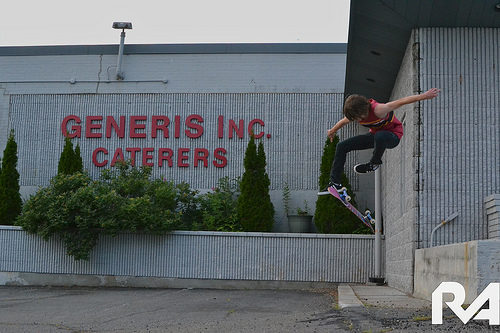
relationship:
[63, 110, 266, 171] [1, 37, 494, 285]
letters on side of building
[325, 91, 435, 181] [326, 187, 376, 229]
guy on top of skateboard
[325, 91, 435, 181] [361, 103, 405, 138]
guy with shirt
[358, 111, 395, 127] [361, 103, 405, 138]
stripes on front of shirt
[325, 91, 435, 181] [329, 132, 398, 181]
guy wearing jeans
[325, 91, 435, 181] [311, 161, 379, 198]
guy wearing shoes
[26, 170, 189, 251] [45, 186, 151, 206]
bushes with flowers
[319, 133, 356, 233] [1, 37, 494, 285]
tree in front of building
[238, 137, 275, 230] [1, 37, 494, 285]
tree in front of building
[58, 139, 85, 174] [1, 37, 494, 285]
tree in front of building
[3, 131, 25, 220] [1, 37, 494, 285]
tree in front of building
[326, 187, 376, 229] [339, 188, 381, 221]
skateboard with wheels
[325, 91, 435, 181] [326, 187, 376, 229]
guy flipping skateboard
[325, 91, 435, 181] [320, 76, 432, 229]
guy doing trick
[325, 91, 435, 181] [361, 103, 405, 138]
guy wearing shirt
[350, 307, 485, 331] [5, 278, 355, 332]
part of pavement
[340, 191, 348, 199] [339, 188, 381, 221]
part of wheels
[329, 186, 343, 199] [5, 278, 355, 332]
part of pavement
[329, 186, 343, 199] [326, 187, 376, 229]
part of skateboard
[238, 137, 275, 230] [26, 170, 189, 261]
tree in bushes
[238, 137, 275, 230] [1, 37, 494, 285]
tree against building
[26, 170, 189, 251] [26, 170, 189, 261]
bushes over bushes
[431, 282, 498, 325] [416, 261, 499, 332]
ra in corner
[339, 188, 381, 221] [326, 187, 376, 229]
wheels on bottom of skateboard